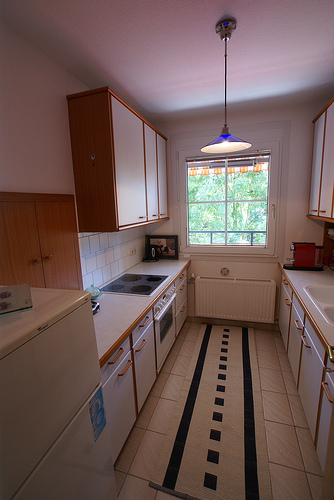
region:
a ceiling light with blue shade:
[198, 22, 252, 154]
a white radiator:
[195, 274, 276, 323]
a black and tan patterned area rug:
[150, 322, 273, 497]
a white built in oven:
[153, 282, 177, 373]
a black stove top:
[98, 271, 167, 296]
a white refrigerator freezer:
[0, 284, 118, 498]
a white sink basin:
[302, 281, 333, 329]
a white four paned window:
[187, 158, 267, 246]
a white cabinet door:
[110, 95, 147, 226]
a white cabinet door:
[144, 118, 160, 220]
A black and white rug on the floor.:
[196, 319, 254, 494]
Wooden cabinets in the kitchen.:
[63, 98, 169, 234]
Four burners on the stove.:
[110, 271, 157, 302]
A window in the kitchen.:
[192, 152, 277, 250]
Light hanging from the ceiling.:
[213, 13, 260, 157]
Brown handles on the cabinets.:
[109, 357, 142, 379]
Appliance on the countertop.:
[275, 231, 328, 276]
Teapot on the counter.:
[138, 238, 163, 266]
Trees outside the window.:
[198, 179, 267, 231]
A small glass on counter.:
[86, 285, 106, 302]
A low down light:
[199, 11, 257, 166]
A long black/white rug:
[133, 315, 283, 486]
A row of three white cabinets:
[53, 83, 178, 233]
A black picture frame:
[139, 229, 177, 258]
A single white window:
[168, 128, 285, 260]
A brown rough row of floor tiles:
[250, 327, 310, 494]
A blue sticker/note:
[76, 381, 111, 441]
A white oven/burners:
[135, 278, 185, 381]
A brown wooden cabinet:
[2, 194, 89, 308]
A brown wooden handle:
[115, 353, 136, 383]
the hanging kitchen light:
[201, 18, 252, 153]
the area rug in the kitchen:
[147, 320, 271, 498]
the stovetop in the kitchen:
[99, 271, 169, 295]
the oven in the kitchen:
[151, 281, 175, 374]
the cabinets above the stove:
[67, 86, 169, 232]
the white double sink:
[302, 282, 333, 324]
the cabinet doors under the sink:
[287, 302, 323, 444]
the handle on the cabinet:
[117, 359, 132, 375]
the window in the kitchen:
[184, 156, 270, 247]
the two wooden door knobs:
[35, 254, 53, 264]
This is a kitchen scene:
[0, 1, 332, 497]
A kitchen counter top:
[84, 255, 191, 364]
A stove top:
[101, 272, 171, 297]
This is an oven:
[153, 281, 178, 373]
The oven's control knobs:
[153, 284, 177, 316]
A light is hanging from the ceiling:
[198, 16, 252, 153]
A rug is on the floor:
[150, 322, 276, 498]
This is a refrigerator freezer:
[0, 284, 119, 498]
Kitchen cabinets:
[66, 84, 171, 232]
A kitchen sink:
[304, 282, 333, 326]